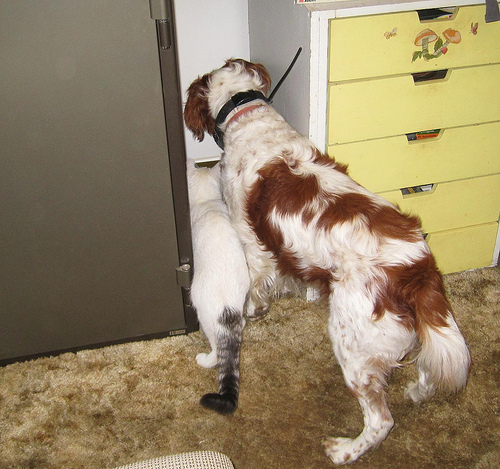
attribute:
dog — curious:
[147, 38, 466, 430]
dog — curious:
[188, 69, 438, 325]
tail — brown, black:
[195, 308, 243, 413]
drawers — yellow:
[337, 34, 495, 278]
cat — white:
[183, 217, 273, 352]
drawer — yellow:
[326, 54, 498, 145]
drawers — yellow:
[326, 70, 499, 163]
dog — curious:
[199, 80, 304, 168]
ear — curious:
[183, 74, 208, 144]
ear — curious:
[241, 55, 274, 85]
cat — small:
[139, 164, 269, 369]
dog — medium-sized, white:
[183, 58, 470, 464]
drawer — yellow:
[327, 60, 498, 142]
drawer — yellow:
[328, 120, 498, 189]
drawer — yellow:
[367, 172, 498, 236]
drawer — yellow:
[429, 223, 498, 276]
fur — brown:
[287, 163, 382, 248]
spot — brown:
[315, 187, 369, 222]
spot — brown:
[367, 200, 423, 240]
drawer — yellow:
[320, 0, 496, 83]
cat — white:
[182, 157, 252, 421]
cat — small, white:
[186, 160, 256, 413]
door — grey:
[2, 7, 198, 367]